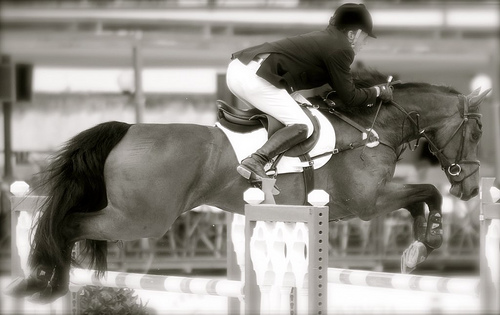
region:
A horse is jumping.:
[21, 87, 479, 270]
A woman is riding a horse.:
[6, 0, 492, 295]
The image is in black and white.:
[0, 0, 498, 312]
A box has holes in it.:
[243, 206, 330, 310]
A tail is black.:
[16, 123, 128, 284]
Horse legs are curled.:
[371, 180, 445, 280]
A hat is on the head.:
[331, 1, 378, 41]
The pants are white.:
[227, 55, 317, 137]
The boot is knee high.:
[233, 122, 308, 191]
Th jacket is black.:
[229, 25, 378, 104]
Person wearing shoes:
[235, 121, 312, 195]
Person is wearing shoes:
[236, 116, 319, 195]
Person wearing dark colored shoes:
[231, 121, 313, 196]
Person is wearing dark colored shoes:
[233, 120, 317, 197]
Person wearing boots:
[232, 121, 313, 198]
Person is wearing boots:
[230, 117, 312, 202]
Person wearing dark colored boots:
[232, 119, 314, 196]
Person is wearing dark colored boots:
[235, 120, 309, 197]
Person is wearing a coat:
[226, 20, 385, 110]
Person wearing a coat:
[231, 25, 384, 112]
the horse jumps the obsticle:
[2, 76, 492, 306]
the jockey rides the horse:
[223, 10, 383, 197]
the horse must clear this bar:
[61, 264, 244, 299]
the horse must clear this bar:
[321, 261, 478, 292]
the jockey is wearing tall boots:
[235, 121, 329, 198]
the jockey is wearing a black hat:
[327, 9, 384, 41]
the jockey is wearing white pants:
[218, 50, 318, 140]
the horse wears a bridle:
[406, 88, 493, 194]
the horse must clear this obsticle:
[6, 174, 499, 311]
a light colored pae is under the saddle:
[210, 90, 341, 180]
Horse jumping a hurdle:
[12, 0, 481, 265]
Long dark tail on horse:
[23, 121, 120, 288]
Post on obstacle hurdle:
[305, 187, 329, 207]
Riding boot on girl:
[237, 122, 309, 187]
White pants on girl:
[226, 60, 319, 129]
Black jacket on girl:
[232, 29, 374, 101]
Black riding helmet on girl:
[332, 5, 384, 39]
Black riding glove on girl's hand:
[376, 83, 393, 100]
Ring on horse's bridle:
[447, 160, 461, 173]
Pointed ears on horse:
[471, 82, 490, 107]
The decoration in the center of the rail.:
[236, 185, 331, 313]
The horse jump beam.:
[66, 253, 243, 305]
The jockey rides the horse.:
[223, 2, 378, 182]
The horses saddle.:
[212, 92, 263, 132]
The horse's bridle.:
[356, 111, 385, 151]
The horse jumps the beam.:
[34, 80, 489, 272]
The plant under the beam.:
[70, 291, 163, 311]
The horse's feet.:
[401, 222, 453, 265]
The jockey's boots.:
[236, 123, 309, 183]